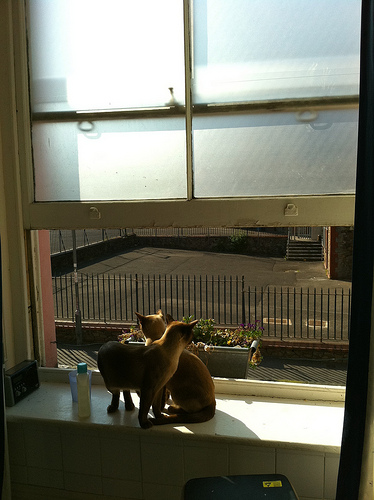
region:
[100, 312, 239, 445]
Two cats sitting on a window sill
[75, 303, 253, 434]
Two animals staring out of an open window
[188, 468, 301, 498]
A black trash can beneath the window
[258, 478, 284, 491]
A small yellow sticker on the black object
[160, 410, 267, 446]
The shadow of the cat on the window sill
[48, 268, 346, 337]
A black metal fence outside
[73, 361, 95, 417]
A bottle resting by the cats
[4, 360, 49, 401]
A small black radio on the window sill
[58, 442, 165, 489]
Square white tiles on the wall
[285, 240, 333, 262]
A small stairwell outside of the window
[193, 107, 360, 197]
A glass window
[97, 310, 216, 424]
Two cats sitting by a window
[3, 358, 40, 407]
A radio on a window sill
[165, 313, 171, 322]
A cat's left ear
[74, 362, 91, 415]
A bottle of some lotion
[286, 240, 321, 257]
Steps surrounded by a fence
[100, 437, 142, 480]
A piece of tile on a wall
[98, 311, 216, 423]
Cats getting cozy by each other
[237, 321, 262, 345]
Purple flowers in a garden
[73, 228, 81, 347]
A pole outside of a building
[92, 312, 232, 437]
two cats on the ledge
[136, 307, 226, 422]
cat sitting on the ledge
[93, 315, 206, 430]
cat standing on the ledge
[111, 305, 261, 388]
planter with plants in it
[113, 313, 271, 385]
planter in the window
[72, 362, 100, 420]
white bottle with a blue cap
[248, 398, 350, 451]
light shining on the ledge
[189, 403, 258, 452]
shadow from the cat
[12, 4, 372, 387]
window is partially open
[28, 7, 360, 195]
frosted glass on the window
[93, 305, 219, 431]
The cats in the window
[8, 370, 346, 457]
The windowsill the cats are on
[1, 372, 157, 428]
The part of the windowsill in shadows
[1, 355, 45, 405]
The radio next to the window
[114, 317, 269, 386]
The planters with the flowers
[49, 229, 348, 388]
The ground made of asphalt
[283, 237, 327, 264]
The stairs in the background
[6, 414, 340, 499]
The white tiles on the wall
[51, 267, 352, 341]
The wrought iron fence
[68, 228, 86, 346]
The large silver post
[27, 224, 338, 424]
Two cats on a window ledge.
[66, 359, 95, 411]
A white bottle with a blue lid.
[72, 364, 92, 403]
Clear liquid in a glass on the window ledge.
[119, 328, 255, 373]
A planter outside of the window.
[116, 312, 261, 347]
Green and brown plants in the planter.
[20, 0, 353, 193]
Window glass covered with white paper.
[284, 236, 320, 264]
A stairway next to a brick wall.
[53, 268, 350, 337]
A metal fence outside of the window.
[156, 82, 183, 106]
A window lock behind paper.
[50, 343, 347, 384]
A shadow of the fence on the ground.